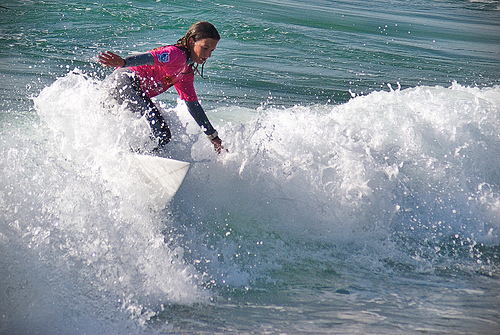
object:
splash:
[2, 65, 500, 335]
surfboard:
[102, 152, 193, 213]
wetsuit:
[101, 43, 219, 152]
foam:
[0, 63, 499, 335]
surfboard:
[107, 153, 197, 225]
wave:
[0, 66, 500, 335]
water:
[0, 0, 499, 335]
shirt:
[115, 45, 200, 102]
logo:
[156, 52, 170, 66]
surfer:
[93, 21, 234, 161]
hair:
[177, 21, 224, 81]